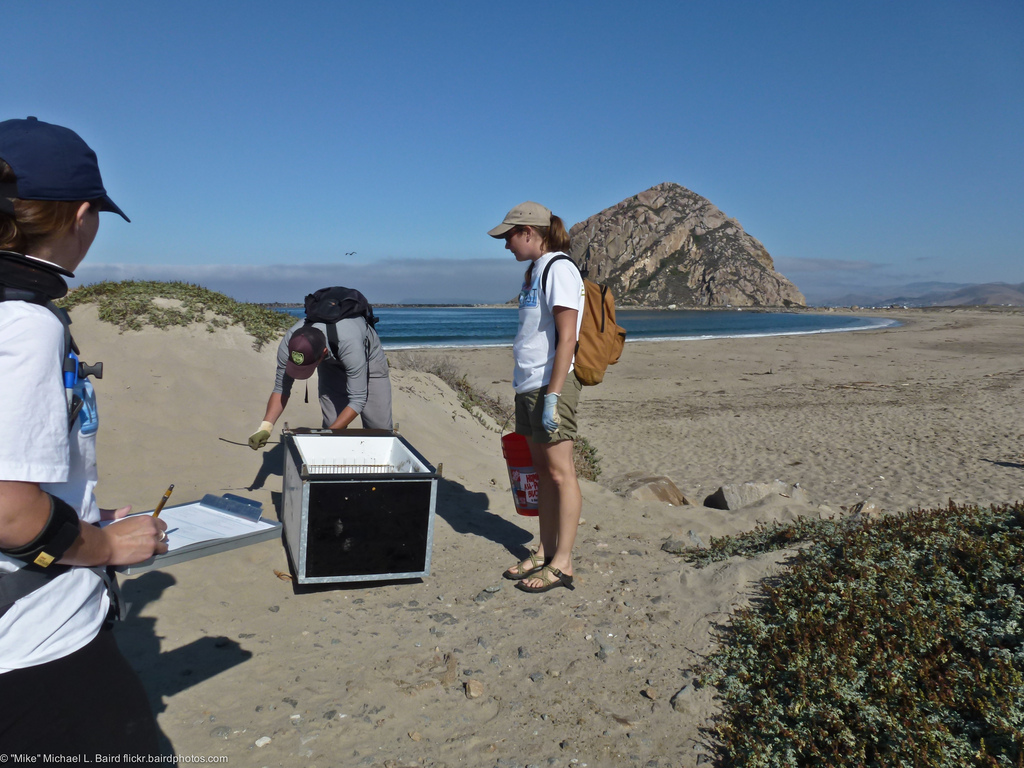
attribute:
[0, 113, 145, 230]
hat — blue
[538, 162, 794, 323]
rock — large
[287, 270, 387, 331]
backpack — black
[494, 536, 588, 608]
sandals — brown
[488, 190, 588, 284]
cap — brown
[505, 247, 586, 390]
shirt — white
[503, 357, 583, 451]
shorts — brown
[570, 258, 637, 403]
backpack — orange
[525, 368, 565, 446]
gloves — blue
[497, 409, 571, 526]
bucket — orange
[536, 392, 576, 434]
gloves — blue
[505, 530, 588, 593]
sandals — gray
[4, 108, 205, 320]
hat — dark blue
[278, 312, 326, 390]
hat — dark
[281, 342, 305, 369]
logo — green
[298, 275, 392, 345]
backpack — black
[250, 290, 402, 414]
man — white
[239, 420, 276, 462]
gloves — green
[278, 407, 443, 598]
container — black, white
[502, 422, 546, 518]
red bucket — with white on it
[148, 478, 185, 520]
pencil — in her hand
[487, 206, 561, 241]
brown cap — on her head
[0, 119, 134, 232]
blue cap — on her head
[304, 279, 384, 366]
black backpack — on his back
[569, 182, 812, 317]
large rock — in the water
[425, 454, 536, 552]
shadow — cast by the woman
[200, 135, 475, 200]
white clouds — in blue sky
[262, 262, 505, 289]
clouds — in the sky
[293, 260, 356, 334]
backpack — black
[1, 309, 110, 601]
shirt — white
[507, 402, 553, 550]
bucket — red